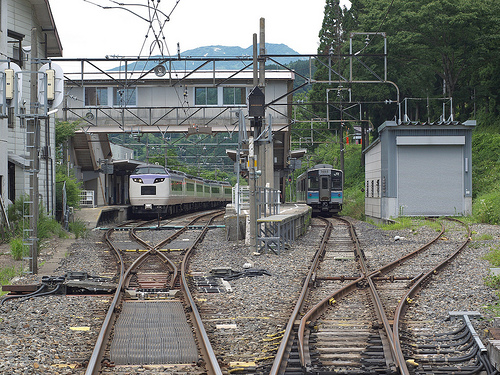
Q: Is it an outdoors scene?
A: Yes, it is outdoors.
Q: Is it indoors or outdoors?
A: It is outdoors.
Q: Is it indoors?
A: No, it is outdoors.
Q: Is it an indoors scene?
A: No, it is outdoors.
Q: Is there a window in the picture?
A: Yes, there is a window.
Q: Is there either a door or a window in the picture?
A: Yes, there is a window.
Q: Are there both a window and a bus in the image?
A: No, there is a window but no buses.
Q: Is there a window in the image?
A: Yes, there is a window.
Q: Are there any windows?
A: Yes, there is a window.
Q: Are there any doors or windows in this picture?
A: Yes, there is a window.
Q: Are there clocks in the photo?
A: No, there are no clocks.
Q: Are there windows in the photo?
A: Yes, there is a window.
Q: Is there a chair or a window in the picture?
A: Yes, there is a window.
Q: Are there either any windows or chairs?
A: Yes, there is a window.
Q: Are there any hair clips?
A: No, there are no hair clips.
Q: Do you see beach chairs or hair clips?
A: No, there are no hair clips or beach chairs.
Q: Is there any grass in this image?
A: Yes, there is grass.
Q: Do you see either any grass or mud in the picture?
A: Yes, there is grass.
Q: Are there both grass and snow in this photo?
A: No, there is grass but no snow.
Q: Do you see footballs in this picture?
A: No, there are no footballs.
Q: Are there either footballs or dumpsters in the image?
A: No, there are no footballs or dumpsters.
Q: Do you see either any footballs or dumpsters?
A: No, there are no footballs or dumpsters.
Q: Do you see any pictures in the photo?
A: No, there are no pictures.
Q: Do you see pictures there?
A: No, there are no pictures.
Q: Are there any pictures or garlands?
A: No, there are no pictures or garlands.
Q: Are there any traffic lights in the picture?
A: Yes, there is a traffic light.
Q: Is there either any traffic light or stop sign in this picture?
A: Yes, there is a traffic light.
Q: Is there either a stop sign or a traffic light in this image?
A: Yes, there is a traffic light.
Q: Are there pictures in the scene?
A: No, there are no pictures.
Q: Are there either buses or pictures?
A: No, there are no pictures or buses.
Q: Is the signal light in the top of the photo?
A: Yes, the signal light is in the top of the image.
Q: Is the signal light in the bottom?
A: No, the signal light is in the top of the image.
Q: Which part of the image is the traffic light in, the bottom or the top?
A: The traffic light is in the top of the image.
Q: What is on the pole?
A: The traffic signal is on the pole.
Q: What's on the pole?
A: The traffic signal is on the pole.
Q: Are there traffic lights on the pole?
A: Yes, there is a traffic light on the pole.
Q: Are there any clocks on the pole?
A: No, there is a traffic light on the pole.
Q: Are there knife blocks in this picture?
A: No, there are no knife blocks.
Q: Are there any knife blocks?
A: No, there are no knife blocks.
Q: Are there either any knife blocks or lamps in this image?
A: No, there are no knife blocks or lamps.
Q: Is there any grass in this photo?
A: Yes, there is grass.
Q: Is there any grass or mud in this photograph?
A: Yes, there is grass.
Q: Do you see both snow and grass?
A: No, there is grass but no snow.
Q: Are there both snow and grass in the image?
A: No, there is grass but no snow.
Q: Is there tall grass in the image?
A: Yes, there is tall grass.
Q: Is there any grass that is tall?
A: Yes, there is grass that is tall.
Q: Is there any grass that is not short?
A: Yes, there is tall grass.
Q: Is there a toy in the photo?
A: No, there are no toys.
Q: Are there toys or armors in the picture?
A: No, there are no toys or armors.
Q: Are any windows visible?
A: Yes, there is a window.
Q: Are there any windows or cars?
A: Yes, there is a window.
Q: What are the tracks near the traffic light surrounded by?
A: The train tracks are surrounded by the gravel.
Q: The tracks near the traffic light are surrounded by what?
A: The train tracks are surrounded by the gravel.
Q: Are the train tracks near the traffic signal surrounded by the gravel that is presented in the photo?
A: Yes, the tracks are surrounded by the gravel.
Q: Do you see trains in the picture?
A: Yes, there is a train.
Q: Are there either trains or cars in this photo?
A: Yes, there is a train.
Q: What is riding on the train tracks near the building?
A: The train is riding on the train tracks.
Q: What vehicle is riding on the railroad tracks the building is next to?
A: The vehicle is a train.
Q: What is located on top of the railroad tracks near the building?
A: The train is on top of the tracks.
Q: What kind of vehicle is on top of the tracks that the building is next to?
A: The vehicle is a train.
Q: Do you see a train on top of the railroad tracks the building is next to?
A: Yes, there is a train on top of the railroad tracks.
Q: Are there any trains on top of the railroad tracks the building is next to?
A: Yes, there is a train on top of the railroad tracks.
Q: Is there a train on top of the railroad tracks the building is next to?
A: Yes, there is a train on top of the railroad tracks.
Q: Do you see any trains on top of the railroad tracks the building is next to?
A: Yes, there is a train on top of the railroad tracks.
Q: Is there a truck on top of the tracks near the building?
A: No, there is a train on top of the train tracks.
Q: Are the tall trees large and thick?
A: Yes, the trees are large and thick.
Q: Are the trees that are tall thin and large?
A: No, the trees are large but thick.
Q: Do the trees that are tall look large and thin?
A: No, the trees are large but thick.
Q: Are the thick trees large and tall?
A: Yes, the trees are large and tall.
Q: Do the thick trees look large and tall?
A: Yes, the trees are large and tall.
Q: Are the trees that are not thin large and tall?
A: Yes, the trees are large and tall.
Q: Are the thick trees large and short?
A: No, the trees are large but tall.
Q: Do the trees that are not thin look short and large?
A: No, the trees are large but tall.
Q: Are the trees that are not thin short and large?
A: No, the trees are large but tall.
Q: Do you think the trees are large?
A: Yes, the trees are large.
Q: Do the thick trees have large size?
A: Yes, the trees are large.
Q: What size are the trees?
A: The trees are large.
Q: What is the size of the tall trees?
A: The trees are large.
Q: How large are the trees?
A: The trees are large.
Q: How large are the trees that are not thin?
A: The trees are large.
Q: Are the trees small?
A: No, the trees are large.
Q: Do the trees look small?
A: No, the trees are large.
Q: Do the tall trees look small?
A: No, the trees are large.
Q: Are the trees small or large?
A: The trees are large.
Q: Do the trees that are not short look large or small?
A: The trees are large.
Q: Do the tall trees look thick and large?
A: Yes, the trees are thick and large.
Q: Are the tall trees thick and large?
A: Yes, the trees are thick and large.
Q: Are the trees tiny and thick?
A: No, the trees are thick but large.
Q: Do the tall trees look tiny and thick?
A: No, the trees are thick but large.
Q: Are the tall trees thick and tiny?
A: No, the trees are thick but large.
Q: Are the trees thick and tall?
A: Yes, the trees are thick and tall.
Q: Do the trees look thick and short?
A: No, the trees are thick but tall.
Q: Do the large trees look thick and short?
A: No, the trees are thick but tall.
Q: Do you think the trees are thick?
A: Yes, the trees are thick.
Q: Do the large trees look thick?
A: Yes, the trees are thick.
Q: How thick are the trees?
A: The trees are thick.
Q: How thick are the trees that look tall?
A: The trees are thick.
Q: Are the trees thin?
A: No, the trees are thick.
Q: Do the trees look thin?
A: No, the trees are thick.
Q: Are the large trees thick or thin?
A: The trees are thick.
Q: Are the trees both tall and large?
A: Yes, the trees are tall and large.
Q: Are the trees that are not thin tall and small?
A: No, the trees are tall but large.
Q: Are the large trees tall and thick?
A: Yes, the trees are tall and thick.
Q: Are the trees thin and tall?
A: No, the trees are tall but thick.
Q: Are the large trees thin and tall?
A: No, the trees are tall but thick.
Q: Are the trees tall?
A: Yes, the trees are tall.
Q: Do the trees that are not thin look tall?
A: Yes, the trees are tall.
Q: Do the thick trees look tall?
A: Yes, the trees are tall.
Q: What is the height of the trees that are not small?
A: The trees are tall.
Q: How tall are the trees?
A: The trees are tall.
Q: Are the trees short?
A: No, the trees are tall.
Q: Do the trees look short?
A: No, the trees are tall.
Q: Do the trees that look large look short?
A: No, the trees are tall.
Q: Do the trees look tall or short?
A: The trees are tall.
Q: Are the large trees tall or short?
A: The trees are tall.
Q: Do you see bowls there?
A: No, there are no bowls.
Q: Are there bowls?
A: No, there are no bowls.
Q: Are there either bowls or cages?
A: No, there are no bowls or cages.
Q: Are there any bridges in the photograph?
A: Yes, there is a bridge.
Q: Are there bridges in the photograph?
A: Yes, there is a bridge.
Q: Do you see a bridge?
A: Yes, there is a bridge.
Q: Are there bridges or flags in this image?
A: Yes, there is a bridge.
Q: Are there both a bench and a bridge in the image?
A: No, there is a bridge but no benches.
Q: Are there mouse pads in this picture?
A: No, there are no mouse pads.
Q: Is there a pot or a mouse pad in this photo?
A: No, there are no mouse pads or pots.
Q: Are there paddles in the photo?
A: No, there are no paddles.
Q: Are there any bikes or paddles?
A: No, there are no paddles or bikes.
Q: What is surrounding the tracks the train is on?
A: The gravel is surrounding the railroad tracks.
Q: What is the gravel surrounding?
A: The gravel is surrounding the tracks.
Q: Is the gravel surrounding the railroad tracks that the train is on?
A: Yes, the gravel is surrounding the railroad tracks.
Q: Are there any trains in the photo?
A: Yes, there is a train.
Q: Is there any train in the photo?
A: Yes, there is a train.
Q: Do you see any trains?
A: Yes, there is a train.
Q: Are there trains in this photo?
A: Yes, there is a train.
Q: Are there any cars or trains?
A: Yes, there is a train.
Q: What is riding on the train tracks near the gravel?
A: The train is riding on the train tracks.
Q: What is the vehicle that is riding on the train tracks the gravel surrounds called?
A: The vehicle is a train.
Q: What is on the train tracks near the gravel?
A: The train is on the train tracks.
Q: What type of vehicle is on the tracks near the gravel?
A: The vehicle is a train.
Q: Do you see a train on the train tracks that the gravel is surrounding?
A: Yes, there is a train on the tracks.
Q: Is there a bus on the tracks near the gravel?
A: No, there is a train on the railroad tracks.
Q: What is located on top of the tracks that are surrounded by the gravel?
A: The train is on top of the train tracks.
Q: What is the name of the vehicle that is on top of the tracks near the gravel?
A: The vehicle is a train.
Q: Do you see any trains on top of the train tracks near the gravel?
A: Yes, there is a train on top of the tracks.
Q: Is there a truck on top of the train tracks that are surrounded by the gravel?
A: No, there is a train on top of the tracks.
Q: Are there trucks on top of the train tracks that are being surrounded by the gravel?
A: No, there is a train on top of the tracks.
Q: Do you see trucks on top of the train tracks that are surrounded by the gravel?
A: No, there is a train on top of the tracks.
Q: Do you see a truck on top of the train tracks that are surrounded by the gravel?
A: No, there is a train on top of the tracks.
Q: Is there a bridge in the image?
A: Yes, there is a bridge.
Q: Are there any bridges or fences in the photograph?
A: Yes, there is a bridge.